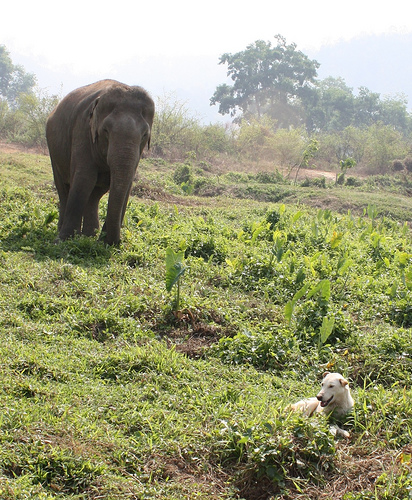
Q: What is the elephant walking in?
A: Grass.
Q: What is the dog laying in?
A: Grass.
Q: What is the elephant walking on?
A: Grass.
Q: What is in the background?
A: Trees.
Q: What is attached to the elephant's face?
A: It's gray trunk.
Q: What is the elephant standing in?
A: Weeds.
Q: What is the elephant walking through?
A: Grass.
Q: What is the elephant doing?
A: Walking.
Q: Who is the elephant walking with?
A: A dog.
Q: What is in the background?
A: Tall trees.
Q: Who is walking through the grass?
A: An elephant.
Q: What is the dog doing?
A: Laying down.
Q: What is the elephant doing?
A: Watching the dog?.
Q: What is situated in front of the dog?
A: A tuft of grass.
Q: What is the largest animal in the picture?
A: Elephant.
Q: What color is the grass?
A: Green.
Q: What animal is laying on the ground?
A: Dog.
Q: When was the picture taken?
A: Daytime.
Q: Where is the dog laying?
A: Grass.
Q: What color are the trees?
A: Green.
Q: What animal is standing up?
A: Elephant.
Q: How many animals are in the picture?
A: Two.